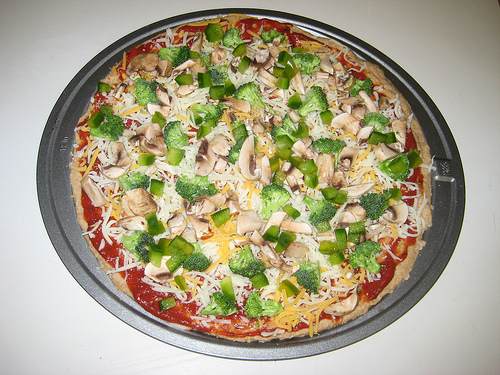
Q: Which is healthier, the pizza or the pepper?
A: The pepper is healthier than the pizza.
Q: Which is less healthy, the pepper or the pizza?
A: The pizza is less healthy than the pepper.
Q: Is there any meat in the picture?
A: No, there is no meat.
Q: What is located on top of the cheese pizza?
A: The mushroom is on top of the pizza.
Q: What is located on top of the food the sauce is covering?
A: The mushroom is on top of the pizza.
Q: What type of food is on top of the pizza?
A: The food is a mushroom.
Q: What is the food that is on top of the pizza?
A: The food is a mushroom.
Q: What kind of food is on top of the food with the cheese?
A: The food is a mushroom.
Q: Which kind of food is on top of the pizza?
A: The food is a mushroom.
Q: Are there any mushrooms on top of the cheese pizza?
A: Yes, there is a mushroom on top of the pizza.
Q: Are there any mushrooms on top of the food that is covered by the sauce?
A: Yes, there is a mushroom on top of the pizza.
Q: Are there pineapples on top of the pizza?
A: No, there is a mushroom on top of the pizza.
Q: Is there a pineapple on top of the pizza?
A: No, there is a mushroom on top of the pizza.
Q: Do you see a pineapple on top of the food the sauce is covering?
A: No, there is a mushroom on top of the pizza.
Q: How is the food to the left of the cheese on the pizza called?
A: The food is a mushroom.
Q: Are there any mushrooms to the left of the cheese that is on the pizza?
A: Yes, there is a mushroom to the left of the cheese.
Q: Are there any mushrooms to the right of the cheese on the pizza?
A: No, the mushroom is to the left of the cheese.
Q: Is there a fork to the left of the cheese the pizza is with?
A: No, there is a mushroom to the left of the cheese.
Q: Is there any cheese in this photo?
A: Yes, there is cheese.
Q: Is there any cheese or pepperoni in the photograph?
A: Yes, there is cheese.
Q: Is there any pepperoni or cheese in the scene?
A: Yes, there is cheese.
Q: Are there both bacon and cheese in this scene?
A: No, there is cheese but no bacon.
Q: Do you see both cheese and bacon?
A: No, there is cheese but no bacon.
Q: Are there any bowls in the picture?
A: No, there are no bowls.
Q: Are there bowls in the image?
A: No, there are no bowls.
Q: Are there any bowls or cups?
A: No, there are no bowls or cups.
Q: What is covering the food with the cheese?
A: The sauce is covering the pizza.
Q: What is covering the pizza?
A: The sauce is covering the pizza.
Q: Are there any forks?
A: No, there are no forks.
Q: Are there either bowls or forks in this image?
A: No, there are no forks or bowls.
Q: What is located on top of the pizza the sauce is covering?
A: The mushroom is on top of the pizza.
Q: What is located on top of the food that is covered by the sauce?
A: The mushroom is on top of the pizza.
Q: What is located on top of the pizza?
A: The mushroom is on top of the pizza.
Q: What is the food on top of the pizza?
A: The food is a mushroom.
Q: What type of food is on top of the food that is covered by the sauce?
A: The food is a mushroom.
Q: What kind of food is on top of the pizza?
A: The food is a mushroom.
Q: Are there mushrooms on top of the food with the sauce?
A: Yes, there is a mushroom on top of the pizza.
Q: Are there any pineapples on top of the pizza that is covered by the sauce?
A: No, there is a mushroom on top of the pizza.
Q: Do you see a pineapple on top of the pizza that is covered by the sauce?
A: No, there is a mushroom on top of the pizza.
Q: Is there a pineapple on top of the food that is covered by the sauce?
A: No, there is a mushroom on top of the pizza.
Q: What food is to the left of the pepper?
A: The food is a mushroom.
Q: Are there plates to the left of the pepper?
A: No, there is a mushroom to the left of the pepper.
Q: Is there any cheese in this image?
A: Yes, there is cheese.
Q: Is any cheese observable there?
A: Yes, there is cheese.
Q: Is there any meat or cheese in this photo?
A: Yes, there is cheese.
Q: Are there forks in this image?
A: No, there are no forks.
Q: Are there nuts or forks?
A: No, there are no forks or nuts.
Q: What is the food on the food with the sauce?
A: The food is cheese.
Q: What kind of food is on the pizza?
A: The food is cheese.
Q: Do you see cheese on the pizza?
A: Yes, there is cheese on the pizza.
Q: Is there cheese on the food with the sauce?
A: Yes, there is cheese on the pizza.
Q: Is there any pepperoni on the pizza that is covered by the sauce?
A: No, there is cheese on the pizza.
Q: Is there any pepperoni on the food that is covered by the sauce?
A: No, there is cheese on the pizza.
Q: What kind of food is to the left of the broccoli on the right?
A: The food is cheese.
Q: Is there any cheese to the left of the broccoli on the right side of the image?
A: Yes, there is cheese to the left of the broccoli.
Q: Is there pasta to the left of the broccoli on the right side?
A: No, there is cheese to the left of the broccoli.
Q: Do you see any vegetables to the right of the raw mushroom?
A: Yes, there is a vegetable to the right of the mushroom.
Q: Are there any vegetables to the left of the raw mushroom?
A: No, the vegetable is to the right of the mushroom.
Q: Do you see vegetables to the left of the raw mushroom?
A: No, the vegetable is to the right of the mushroom.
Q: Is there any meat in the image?
A: No, there is no meat.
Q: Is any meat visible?
A: No, there is no meat.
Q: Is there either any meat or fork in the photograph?
A: No, there are no meat or forks.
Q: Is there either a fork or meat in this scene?
A: No, there are no meat or forks.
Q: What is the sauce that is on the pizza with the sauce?
A: The sauce is tomato sauce.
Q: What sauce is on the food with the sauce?
A: The sauce is tomato sauce.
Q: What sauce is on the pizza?
A: The sauce is tomato sauce.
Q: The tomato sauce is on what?
A: The tomato sauce is on the pizza.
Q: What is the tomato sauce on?
A: The tomato sauce is on the pizza.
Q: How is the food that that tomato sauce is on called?
A: The food is a pizza.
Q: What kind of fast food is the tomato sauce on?
A: The tomato sauce is on the pizza.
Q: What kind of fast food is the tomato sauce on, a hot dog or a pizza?
A: The tomato sauce is on a pizza.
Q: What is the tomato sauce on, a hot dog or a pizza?
A: The tomato sauce is on a pizza.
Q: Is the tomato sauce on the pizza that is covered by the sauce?
A: Yes, the tomato sauce is on the pizza.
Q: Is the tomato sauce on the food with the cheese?
A: Yes, the tomato sauce is on the pizza.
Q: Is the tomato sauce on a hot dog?
A: No, the tomato sauce is on the pizza.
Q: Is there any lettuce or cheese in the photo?
A: Yes, there is cheese.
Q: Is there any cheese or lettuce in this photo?
A: Yes, there is cheese.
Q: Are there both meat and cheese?
A: No, there is cheese but no meat.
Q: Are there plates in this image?
A: No, there are no plates.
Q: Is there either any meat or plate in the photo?
A: No, there are no plates or meat.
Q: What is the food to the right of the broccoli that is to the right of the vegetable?
A: The food is cheese.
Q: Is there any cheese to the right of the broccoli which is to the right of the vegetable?
A: Yes, there is cheese to the right of the broccoli.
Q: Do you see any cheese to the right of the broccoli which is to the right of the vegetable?
A: Yes, there is cheese to the right of the broccoli.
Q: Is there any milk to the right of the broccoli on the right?
A: No, there is cheese to the right of the broccoli.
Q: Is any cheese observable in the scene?
A: Yes, there is cheese.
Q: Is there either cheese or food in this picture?
A: Yes, there is cheese.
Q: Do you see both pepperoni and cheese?
A: No, there is cheese but no pepperoni.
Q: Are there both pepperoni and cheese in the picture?
A: No, there is cheese but no pepperoni.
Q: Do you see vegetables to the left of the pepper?
A: Yes, there is a vegetable to the left of the pepper.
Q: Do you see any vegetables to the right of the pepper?
A: No, the vegetable is to the left of the pepper.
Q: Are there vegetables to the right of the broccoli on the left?
A: Yes, there is a vegetable to the right of the broccoli.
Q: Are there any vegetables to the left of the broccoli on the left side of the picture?
A: No, the vegetable is to the right of the broccoli.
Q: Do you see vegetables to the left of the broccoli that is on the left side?
A: No, the vegetable is to the right of the broccoli.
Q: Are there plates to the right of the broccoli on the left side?
A: No, there is a vegetable to the right of the broccoli.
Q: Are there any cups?
A: No, there are no cups.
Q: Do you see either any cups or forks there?
A: No, there are no cups or forks.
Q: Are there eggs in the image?
A: No, there are no eggs.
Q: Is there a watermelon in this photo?
A: No, there are no watermelons.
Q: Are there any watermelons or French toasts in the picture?
A: No, there are no watermelons or French toasts.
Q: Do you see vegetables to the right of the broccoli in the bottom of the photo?
A: Yes, there is a vegetable to the right of the broccoli.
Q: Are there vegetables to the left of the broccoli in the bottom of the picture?
A: No, the vegetable is to the right of the broccoli.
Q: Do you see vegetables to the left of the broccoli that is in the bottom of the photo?
A: No, the vegetable is to the right of the broccoli.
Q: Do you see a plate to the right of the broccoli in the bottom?
A: No, there is a vegetable to the right of the broccoli.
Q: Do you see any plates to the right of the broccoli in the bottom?
A: No, there is a vegetable to the right of the broccoli.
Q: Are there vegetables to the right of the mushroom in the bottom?
A: Yes, there is a vegetable to the right of the mushroom.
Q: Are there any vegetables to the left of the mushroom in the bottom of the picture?
A: No, the vegetable is to the right of the mushroom.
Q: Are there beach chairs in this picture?
A: No, there are no beach chairs.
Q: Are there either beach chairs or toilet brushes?
A: No, there are no beach chairs or toilet brushes.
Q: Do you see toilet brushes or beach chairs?
A: No, there are no beach chairs or toilet brushes.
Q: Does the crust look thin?
A: Yes, the crust is thin.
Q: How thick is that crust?
A: The crust is thin.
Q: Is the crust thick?
A: No, the crust is thin.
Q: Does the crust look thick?
A: No, the crust is thin.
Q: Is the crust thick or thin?
A: The crust is thin.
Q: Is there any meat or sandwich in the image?
A: No, there are no meat or sandwiches.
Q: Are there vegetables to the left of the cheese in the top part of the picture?
A: Yes, there is a vegetable to the left of the cheese.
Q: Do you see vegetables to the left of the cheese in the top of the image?
A: Yes, there is a vegetable to the left of the cheese.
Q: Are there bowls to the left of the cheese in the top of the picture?
A: No, there is a vegetable to the left of the cheese.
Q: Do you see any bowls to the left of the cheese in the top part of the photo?
A: No, there is a vegetable to the left of the cheese.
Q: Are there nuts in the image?
A: No, there are no nuts.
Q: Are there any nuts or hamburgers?
A: No, there are no nuts or hamburgers.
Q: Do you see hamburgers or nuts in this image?
A: No, there are no nuts or hamburgers.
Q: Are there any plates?
A: No, there are no plates.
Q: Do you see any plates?
A: No, there are no plates.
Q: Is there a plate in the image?
A: No, there are no plates.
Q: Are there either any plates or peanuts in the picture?
A: No, there are no plates or peanuts.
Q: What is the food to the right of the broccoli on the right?
A: The food is a mushroom.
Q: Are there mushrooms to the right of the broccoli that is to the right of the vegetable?
A: Yes, there is a mushroom to the right of the broccoli.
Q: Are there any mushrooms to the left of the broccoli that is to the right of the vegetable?
A: No, the mushroom is to the right of the broccoli.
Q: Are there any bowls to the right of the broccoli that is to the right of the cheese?
A: No, there is a mushroom to the right of the broccoli.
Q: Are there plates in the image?
A: No, there are no plates.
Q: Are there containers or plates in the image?
A: No, there are no plates or containers.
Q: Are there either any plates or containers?
A: No, there are no plates or containers.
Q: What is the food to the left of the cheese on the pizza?
A: The food is a mushroom.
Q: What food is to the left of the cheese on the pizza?
A: The food is a mushroom.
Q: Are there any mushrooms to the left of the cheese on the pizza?
A: Yes, there is a mushroom to the left of the cheese.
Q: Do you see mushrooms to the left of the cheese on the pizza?
A: Yes, there is a mushroom to the left of the cheese.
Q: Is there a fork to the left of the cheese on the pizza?
A: No, there is a mushroom to the left of the cheese.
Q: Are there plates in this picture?
A: No, there are no plates.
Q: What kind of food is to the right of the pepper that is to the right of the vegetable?
A: The food is a mushroom.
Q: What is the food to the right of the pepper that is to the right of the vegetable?
A: The food is a mushroom.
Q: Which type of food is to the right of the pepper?
A: The food is a mushroom.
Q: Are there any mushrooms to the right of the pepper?
A: Yes, there is a mushroom to the right of the pepper.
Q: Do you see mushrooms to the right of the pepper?
A: Yes, there is a mushroom to the right of the pepper.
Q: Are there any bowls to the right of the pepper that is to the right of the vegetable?
A: No, there is a mushroom to the right of the pepper.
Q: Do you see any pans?
A: Yes, there is a pan.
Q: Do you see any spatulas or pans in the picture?
A: Yes, there is a pan.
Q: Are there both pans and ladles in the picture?
A: No, there is a pan but no ladles.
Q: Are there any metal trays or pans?
A: Yes, there is a metal pan.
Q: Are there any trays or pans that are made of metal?
A: Yes, the pan is made of metal.